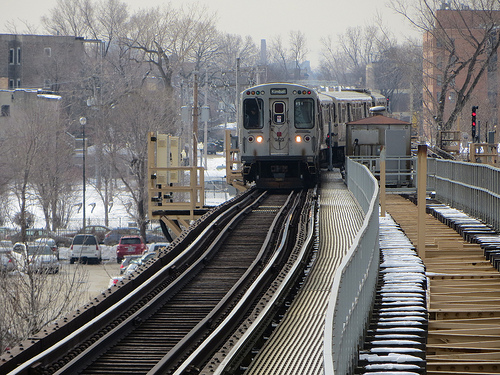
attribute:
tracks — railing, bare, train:
[122, 199, 336, 318]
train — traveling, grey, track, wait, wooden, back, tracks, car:
[201, 60, 422, 177]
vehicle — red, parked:
[99, 228, 153, 271]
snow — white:
[69, 189, 88, 212]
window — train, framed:
[243, 94, 276, 146]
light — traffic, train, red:
[225, 128, 279, 182]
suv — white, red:
[53, 228, 110, 277]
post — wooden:
[160, 101, 219, 209]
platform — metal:
[347, 153, 421, 288]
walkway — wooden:
[376, 135, 496, 318]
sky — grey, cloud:
[230, 5, 252, 27]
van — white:
[52, 210, 102, 267]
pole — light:
[37, 114, 116, 237]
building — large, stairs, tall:
[403, 3, 497, 146]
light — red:
[474, 84, 495, 149]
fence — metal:
[332, 124, 440, 349]